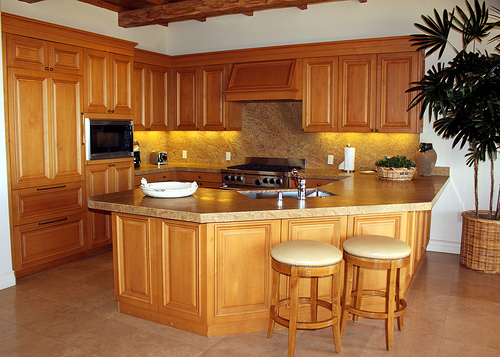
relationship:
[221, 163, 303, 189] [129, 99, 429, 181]
oven against wall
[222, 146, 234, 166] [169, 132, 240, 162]
socket on wall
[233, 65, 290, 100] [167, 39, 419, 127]
hood blended with cabinets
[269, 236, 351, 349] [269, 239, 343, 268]
bar stool has cushions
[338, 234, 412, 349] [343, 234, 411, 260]
bar stool has cushion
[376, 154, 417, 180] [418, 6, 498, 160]
basket has plants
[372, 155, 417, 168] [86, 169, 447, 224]
greenery on counter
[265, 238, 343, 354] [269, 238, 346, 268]
bar stool have cushions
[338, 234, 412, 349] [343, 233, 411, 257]
bar stool have cushion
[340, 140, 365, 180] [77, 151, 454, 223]
paper towels are on counter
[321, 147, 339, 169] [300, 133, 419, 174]
socket on wall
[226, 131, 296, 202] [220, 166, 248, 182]
oven has knobs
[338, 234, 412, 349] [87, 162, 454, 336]
bar stool near counter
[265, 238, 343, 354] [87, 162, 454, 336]
bar stool near counter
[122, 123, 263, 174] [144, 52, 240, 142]
lighting below cabinets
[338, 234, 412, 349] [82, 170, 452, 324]
bar stool near counter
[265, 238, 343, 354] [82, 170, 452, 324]
bar stool near counter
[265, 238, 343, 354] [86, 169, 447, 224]
bar stool near counter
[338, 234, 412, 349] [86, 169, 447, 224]
bar stool near counter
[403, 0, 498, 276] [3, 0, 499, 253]
plant against wall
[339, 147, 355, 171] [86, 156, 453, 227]
paper towels on counter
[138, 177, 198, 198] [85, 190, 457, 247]
bowl on counter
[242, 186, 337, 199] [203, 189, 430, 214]
sink in counter